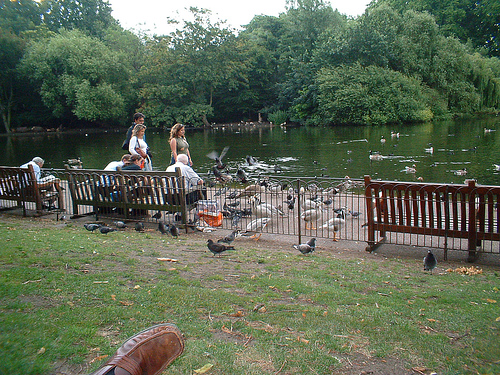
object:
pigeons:
[169, 221, 182, 239]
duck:
[368, 148, 380, 155]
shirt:
[172, 135, 189, 154]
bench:
[360, 174, 498, 259]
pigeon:
[203, 236, 238, 258]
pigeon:
[293, 233, 318, 253]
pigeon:
[421, 247, 437, 272]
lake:
[8, 122, 498, 188]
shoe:
[94, 321, 189, 374]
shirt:
[159, 161, 203, 195]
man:
[99, 152, 133, 194]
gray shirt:
[102, 160, 122, 173]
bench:
[63, 165, 207, 232]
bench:
[0, 165, 62, 216]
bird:
[291, 237, 317, 258]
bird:
[207, 145, 233, 170]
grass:
[0, 213, 500, 373]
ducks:
[379, 135, 388, 144]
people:
[128, 123, 151, 172]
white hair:
[177, 153, 189, 165]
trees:
[144, 17, 261, 121]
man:
[16, 153, 60, 211]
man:
[162, 154, 208, 208]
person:
[122, 111, 145, 152]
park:
[0, 0, 500, 375]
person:
[166, 123, 191, 164]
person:
[92, 153, 130, 197]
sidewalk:
[2, 173, 500, 254]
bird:
[312, 210, 350, 241]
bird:
[297, 201, 327, 232]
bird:
[247, 194, 284, 220]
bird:
[279, 187, 299, 211]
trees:
[72, 75, 124, 128]